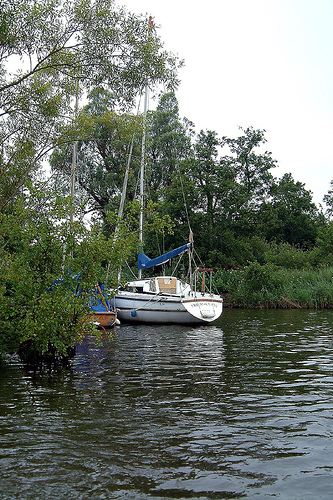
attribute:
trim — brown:
[150, 277, 176, 303]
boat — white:
[101, 266, 234, 327]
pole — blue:
[137, 237, 190, 261]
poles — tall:
[99, 11, 155, 291]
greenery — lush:
[6, 2, 331, 333]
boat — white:
[98, 271, 222, 333]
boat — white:
[101, 271, 231, 331]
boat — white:
[93, 266, 223, 330]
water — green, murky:
[0, 307, 326, 498]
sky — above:
[213, 40, 283, 92]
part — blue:
[133, 241, 198, 273]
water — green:
[97, 357, 269, 462]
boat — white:
[76, 234, 229, 339]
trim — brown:
[117, 290, 234, 331]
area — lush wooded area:
[170, 149, 323, 322]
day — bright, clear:
[18, 33, 330, 422]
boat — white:
[70, 65, 258, 348]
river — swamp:
[55, 331, 303, 497]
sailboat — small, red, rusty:
[45, 257, 147, 347]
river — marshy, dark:
[33, 312, 318, 497]